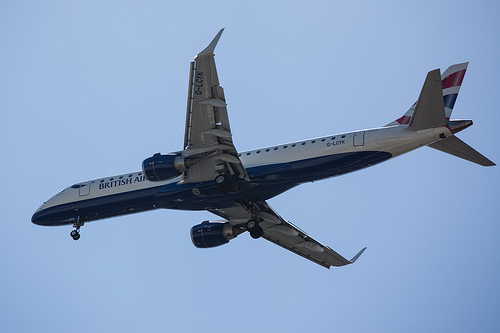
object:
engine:
[140, 153, 187, 182]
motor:
[191, 220, 254, 248]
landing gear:
[212, 172, 239, 194]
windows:
[99, 178, 107, 184]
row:
[82, 133, 347, 188]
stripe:
[438, 68, 467, 90]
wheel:
[213, 174, 227, 190]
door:
[353, 130, 366, 147]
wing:
[413, 67, 446, 127]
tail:
[376, 61, 499, 170]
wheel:
[246, 220, 263, 239]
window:
[255, 149, 261, 154]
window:
[291, 143, 295, 148]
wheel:
[67, 230, 79, 241]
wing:
[180, 27, 248, 188]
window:
[329, 136, 336, 141]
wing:
[210, 203, 369, 270]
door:
[78, 181, 90, 197]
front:
[29, 173, 133, 239]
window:
[119, 175, 124, 180]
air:
[0, 1, 497, 333]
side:
[31, 121, 416, 214]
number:
[193, 83, 205, 87]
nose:
[23, 182, 76, 229]